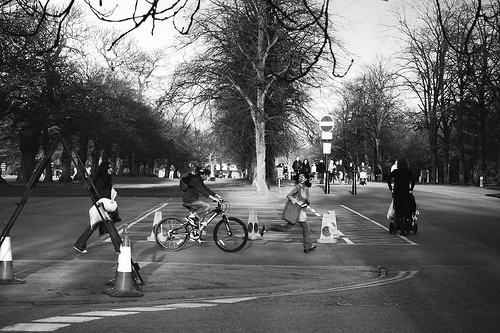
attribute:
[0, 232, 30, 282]
safety cone — large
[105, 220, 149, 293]
cone — small safety 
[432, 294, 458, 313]
beer — Glass 